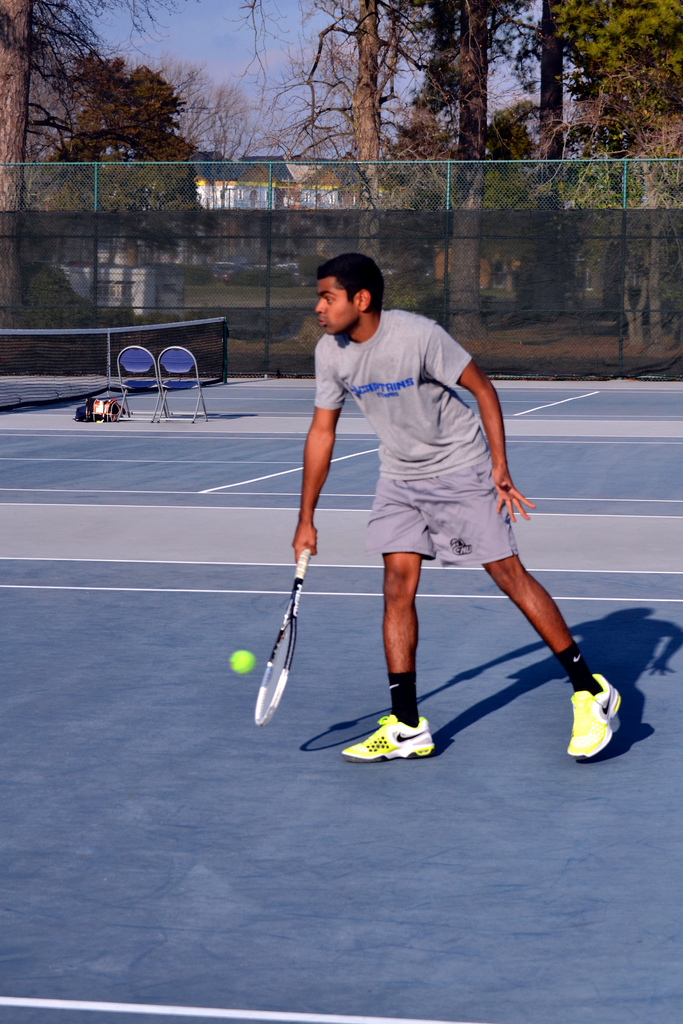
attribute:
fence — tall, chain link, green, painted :
[2, 152, 681, 395]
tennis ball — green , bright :
[229, 643, 256, 685]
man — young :
[228, 232, 630, 780]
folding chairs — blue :
[112, 336, 220, 424]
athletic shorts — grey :
[358, 465, 524, 565]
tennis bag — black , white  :
[68, 392, 127, 424]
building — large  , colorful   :
[110, 135, 410, 287]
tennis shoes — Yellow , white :
[331, 666, 634, 762]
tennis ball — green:
[225, 635, 257, 679]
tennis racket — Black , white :
[240, 540, 324, 726]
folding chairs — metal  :
[98, 332, 235, 428]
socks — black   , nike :
[379, 628, 609, 726]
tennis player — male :
[273, 239, 633, 766]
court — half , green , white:
[1, 368, 644, 1019]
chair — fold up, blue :
[110, 335, 218, 433]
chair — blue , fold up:
[155, 340, 224, 428]